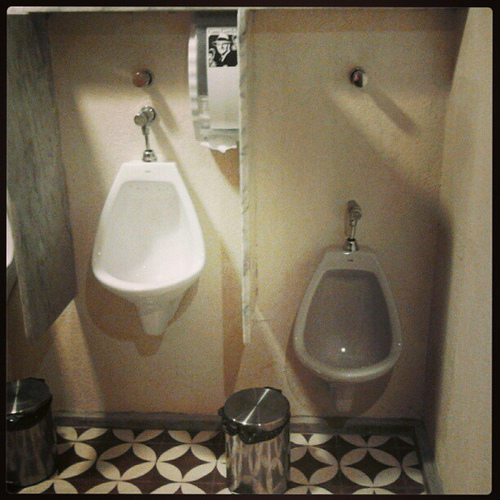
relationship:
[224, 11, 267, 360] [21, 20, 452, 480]
stall wall in bathroom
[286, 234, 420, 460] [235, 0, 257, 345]
urinal attached to stall wall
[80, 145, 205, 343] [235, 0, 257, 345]
urinal attached to stall wall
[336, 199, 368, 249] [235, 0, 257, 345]
pipe attached to stall wall